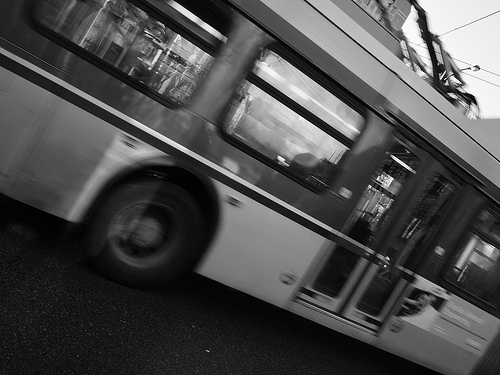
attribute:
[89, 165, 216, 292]
tire — large, rubber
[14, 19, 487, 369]
picture — black and white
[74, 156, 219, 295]
tire — black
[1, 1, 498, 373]
bus — white, large, passenger bus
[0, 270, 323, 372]
street — black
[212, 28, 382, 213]
window — closed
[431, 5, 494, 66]
lines — power lines